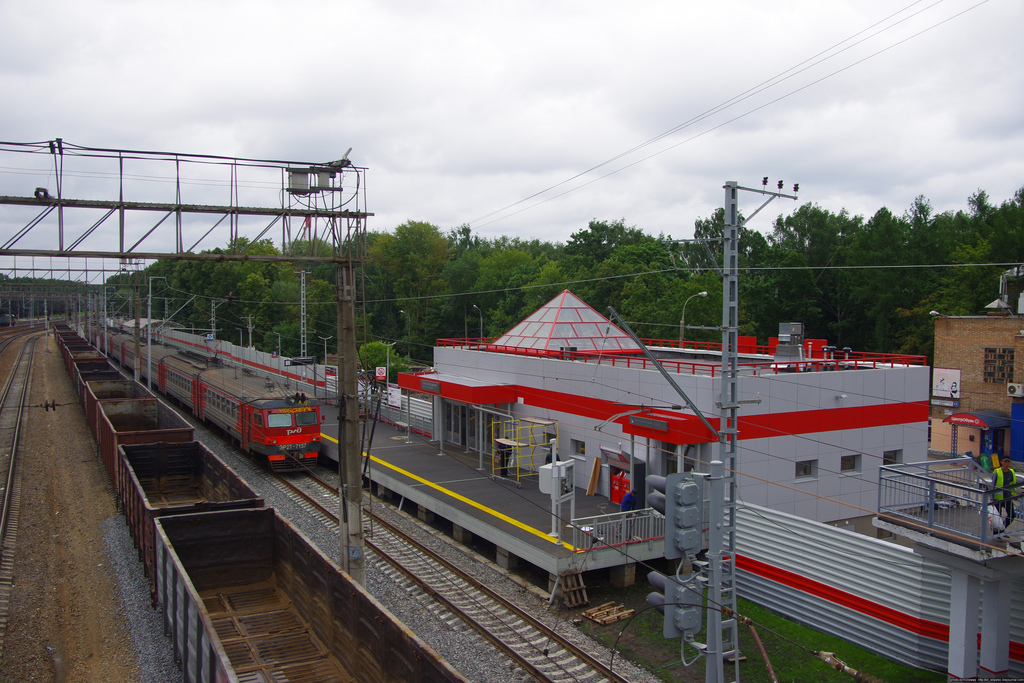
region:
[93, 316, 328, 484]
The red train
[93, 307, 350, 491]
A red train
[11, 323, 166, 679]
The brown dirt near the track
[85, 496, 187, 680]
The gray gravel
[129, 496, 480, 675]
A metal container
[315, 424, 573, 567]
The yellow line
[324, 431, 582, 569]
A yellow line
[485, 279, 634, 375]
The pointed roof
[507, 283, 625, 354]
A pointed roof on the gray building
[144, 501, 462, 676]
train car on railroad track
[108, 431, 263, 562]
train car on railroad track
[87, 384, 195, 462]
train car on railroad track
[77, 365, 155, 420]
train car on railroad track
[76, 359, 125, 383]
train car on railroad track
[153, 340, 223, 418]
train car on railroad track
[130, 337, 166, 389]
train car on railroad track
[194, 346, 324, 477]
train car on railroad track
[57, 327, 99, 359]
train car on railroad track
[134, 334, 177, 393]
train car on railroad track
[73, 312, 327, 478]
long grey and red train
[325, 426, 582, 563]
straight yellow line painted on a railway platform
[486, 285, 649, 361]
red and grey pyramid structure on the roof of a train station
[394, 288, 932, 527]
red and grey train station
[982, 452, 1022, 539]
man is wearing a high visibility vest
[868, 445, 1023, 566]
man is standing on a concrete platform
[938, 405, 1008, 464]
arched porch outside a building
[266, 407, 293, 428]
front windshield on a train engine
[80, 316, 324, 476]
Red and silver train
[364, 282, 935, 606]
Red and silver train station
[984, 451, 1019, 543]
Man wearing bright green vest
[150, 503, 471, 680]
Empty cargo train car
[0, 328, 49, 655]
Empty train track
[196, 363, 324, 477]
Lead car of the train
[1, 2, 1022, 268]
Sky completely covered in clouds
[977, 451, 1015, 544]
Man carrying a trash bag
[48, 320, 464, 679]
Line of empty cargo train cars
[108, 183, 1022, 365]
Large group of trees behind the building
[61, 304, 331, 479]
Train on the tracks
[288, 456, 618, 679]
Track in front of the train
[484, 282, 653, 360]
Pyramid shaped roof on the building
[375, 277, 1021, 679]
Building is grey and red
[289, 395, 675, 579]
Platform in front of building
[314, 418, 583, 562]
Yellow line on platform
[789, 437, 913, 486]
Three windows on side of building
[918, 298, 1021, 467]
Brown brick building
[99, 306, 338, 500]
red train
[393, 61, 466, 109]
white clouds in blue sky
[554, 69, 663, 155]
white clouds in blue sky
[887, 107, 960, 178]
white clouds in blue sky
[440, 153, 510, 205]
white clouds in blue sky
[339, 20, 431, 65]
white clouds in blue sky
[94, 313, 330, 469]
red and silver electric train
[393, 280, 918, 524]
grey and red train station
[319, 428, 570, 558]
yellow line along edge of platform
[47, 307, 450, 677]
empty coal cars on track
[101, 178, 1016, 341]
TOps of trees behind train station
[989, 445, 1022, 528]
man stands at a railing wearing a neon yellow vest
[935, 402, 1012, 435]
awning over a doorway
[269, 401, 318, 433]
split windshield on train engine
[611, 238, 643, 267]
green leaves on the tree